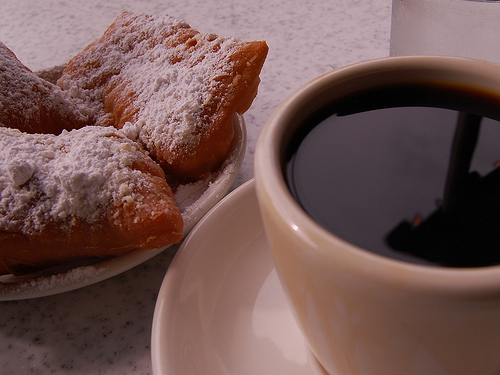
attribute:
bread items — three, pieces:
[0, 5, 270, 265]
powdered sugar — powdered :
[57, 152, 99, 188]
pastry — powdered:
[54, 9, 268, 179]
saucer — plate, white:
[150, 177, 331, 372]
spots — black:
[2, 0, 401, 374]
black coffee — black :
[278, 72, 498, 277]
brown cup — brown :
[270, 201, 498, 356]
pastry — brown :
[1, 9, 266, 254]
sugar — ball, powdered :
[3, 158, 37, 190]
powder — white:
[103, 37, 193, 142]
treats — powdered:
[0, 33, 260, 235]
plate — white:
[131, 174, 323, 374]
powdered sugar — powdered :
[1, 127, 173, 244]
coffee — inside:
[311, 102, 498, 199]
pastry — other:
[3, 123, 179, 251]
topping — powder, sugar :
[2, 124, 135, 224]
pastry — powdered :
[0, 119, 183, 279]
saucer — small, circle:
[149, 161, 498, 373]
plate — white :
[5, 70, 243, 300]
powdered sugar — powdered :
[22, 264, 102, 288]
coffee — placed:
[155, 52, 499, 373]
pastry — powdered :
[0, 33, 93, 135]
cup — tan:
[252, 54, 492, 372]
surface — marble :
[4, 0, 397, 368]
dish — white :
[0, 50, 252, 309]